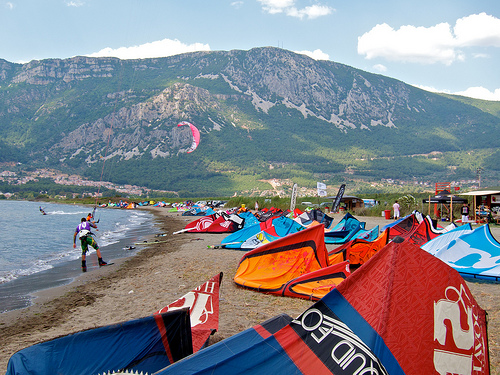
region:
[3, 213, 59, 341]
Water in the ocean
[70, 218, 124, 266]
Man standing on sand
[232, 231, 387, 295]
Red and orange kite on a beach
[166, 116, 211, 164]
Red and gray kite in the sky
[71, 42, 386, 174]
Green and brown mountain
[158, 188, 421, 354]
Kites on a beach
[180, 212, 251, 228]
Red and white kite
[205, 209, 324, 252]
Blue and red kite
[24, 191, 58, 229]
Man kite surfing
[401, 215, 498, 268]
Blue and white kite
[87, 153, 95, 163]
a tree in a distance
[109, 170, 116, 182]
a tree in a distance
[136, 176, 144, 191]
a tree in a distance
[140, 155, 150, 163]
a tree in a distance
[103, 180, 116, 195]
a tree in a distance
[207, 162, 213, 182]
a tree in a distance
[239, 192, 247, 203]
a tree in a distance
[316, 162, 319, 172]
a tree in a distance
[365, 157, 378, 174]
a tree in a distance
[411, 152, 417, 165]
a tree in a distance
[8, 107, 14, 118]
a tree in a distance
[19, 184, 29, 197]
a tree in a distance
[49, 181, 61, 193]
a tree in a distance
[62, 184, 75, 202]
a tree in a distance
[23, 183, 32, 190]
a tree in a distance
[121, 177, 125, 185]
a tree in a distance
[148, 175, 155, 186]
a tree in a distance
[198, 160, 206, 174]
a tree in a distance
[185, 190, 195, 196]
a tree in a distance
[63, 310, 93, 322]
a footstep in the sand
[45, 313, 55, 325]
a footstep in the sand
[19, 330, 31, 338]
a footstep in the sand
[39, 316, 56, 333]
a footstep in the sand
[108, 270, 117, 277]
a footstep in the sand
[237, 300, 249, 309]
a footstep in the sand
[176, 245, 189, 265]
a footstep in the sand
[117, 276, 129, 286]
a footstep in the sand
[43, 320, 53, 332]
a footstep in the sand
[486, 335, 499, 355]
a footstep in the sand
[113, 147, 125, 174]
a tree in a distance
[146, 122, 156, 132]
a tree in a distance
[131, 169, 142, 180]
a tree in a distance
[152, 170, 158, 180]
a tree in a distance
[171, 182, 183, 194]
a tree in a distance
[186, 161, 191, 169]
a tree in a distance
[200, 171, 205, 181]
a tree in a distance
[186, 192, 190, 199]
a tree in a distance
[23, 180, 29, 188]
a tree in a distance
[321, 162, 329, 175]
a tree in a distance